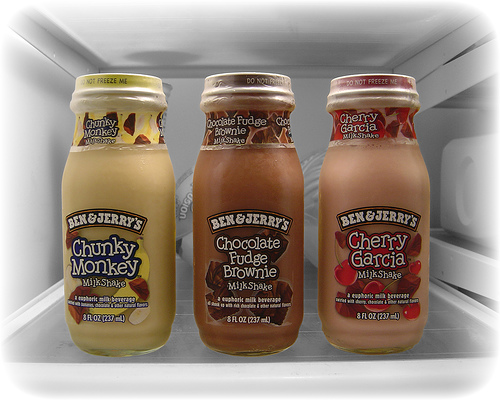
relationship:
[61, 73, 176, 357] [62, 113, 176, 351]
bottle holds milkshake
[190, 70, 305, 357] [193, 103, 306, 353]
bottle holds milkshake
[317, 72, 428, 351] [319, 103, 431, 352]
bottle holds milkshake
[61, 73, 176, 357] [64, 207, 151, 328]
bottle has label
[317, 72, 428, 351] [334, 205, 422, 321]
bottle has label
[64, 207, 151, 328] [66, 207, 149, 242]
label has brand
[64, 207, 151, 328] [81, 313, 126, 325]
label has size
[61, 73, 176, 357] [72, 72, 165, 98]
bottle has lid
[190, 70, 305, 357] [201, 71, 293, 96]
bottle has lid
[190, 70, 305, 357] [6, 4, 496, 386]
bottle in cooler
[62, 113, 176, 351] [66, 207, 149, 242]
milkshake has brand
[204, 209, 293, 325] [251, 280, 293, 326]
label has brownie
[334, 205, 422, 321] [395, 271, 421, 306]
label has chocolate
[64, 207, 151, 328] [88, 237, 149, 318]
label has banana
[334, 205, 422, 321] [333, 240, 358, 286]
label has cherry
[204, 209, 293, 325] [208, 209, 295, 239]
label has brand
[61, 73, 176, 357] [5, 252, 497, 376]
bottle on shelf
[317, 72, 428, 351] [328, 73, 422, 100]
bottle has lid